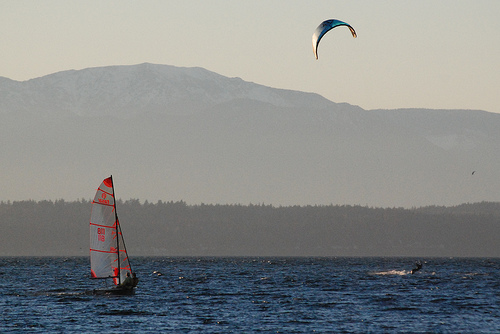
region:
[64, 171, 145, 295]
orange sail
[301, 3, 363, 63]
kite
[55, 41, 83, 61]
white clouds in blue sky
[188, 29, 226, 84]
white clouds in blue sky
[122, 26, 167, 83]
white clouds in blue sky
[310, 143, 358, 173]
white clouds in blue sky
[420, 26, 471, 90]
white clouds in blue sky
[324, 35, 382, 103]
white clouds in blue sky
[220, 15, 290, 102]
white clouds in blue sky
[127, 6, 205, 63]
white clouds in blue sky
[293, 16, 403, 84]
an object in air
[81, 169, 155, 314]
a red cloth in air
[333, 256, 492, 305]
a disturbance in water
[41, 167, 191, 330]
a boat in water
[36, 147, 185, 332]
an old boat in water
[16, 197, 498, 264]
a set of trees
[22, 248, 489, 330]
a cool blue sea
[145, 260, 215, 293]
a white objects in water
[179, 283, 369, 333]
riddle in the water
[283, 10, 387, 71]
a parachuate in air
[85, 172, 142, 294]
Sailboat on open water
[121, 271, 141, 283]
Two people in sailboat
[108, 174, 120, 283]
Main mast of sailboat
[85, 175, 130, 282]
Red and white main sail of boat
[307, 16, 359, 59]
Parasail in the air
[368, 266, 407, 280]
Wake caused by man parasailing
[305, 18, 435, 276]
Man using a parasail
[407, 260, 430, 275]
Man parasailing on water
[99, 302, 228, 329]
Small waves on ocean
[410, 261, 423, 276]
Wetsuit on man parasailing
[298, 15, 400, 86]
Kite in the sky.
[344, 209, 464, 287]
Person in the water.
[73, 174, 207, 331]
Boat on the water.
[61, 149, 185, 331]
White and red sail.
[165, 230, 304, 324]
Waves in the water.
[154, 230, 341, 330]
Ocean with waves.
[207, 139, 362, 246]
Trees behind the blue water.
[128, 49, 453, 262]
Mountains in the background.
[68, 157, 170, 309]
Boat in the blue water.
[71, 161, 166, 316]
Colorful sail on the boat.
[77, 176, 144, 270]
white and orange sail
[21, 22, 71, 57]
white clouds in blue sky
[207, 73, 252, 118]
white clouds in blue sky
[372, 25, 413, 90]
white clouds in blue sky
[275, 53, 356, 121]
white clouds in blue sky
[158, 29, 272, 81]
white clouds in blue sky